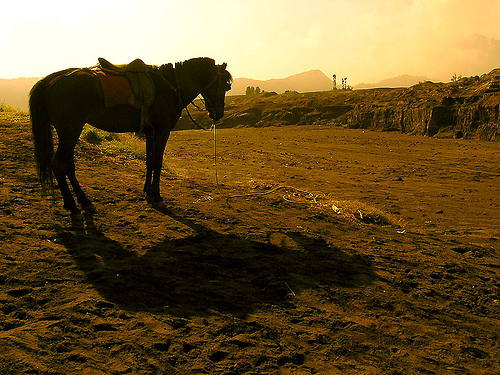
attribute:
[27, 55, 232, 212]
horse — brown, silhouetted, pictured, standing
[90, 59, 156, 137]
saddle — small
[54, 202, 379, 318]
shadow of horse — dark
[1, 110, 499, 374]
dirt ground — in the field, harsh, short, brown, green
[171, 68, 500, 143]
rocky edge — in the field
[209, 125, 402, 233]
rope — hanging, long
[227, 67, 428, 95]
mountains — faded, on the horizon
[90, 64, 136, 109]
blanket — orange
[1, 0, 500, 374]
landscape — harsh, rocky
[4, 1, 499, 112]
sky — cloudy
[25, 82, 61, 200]
horse tail — long, horse's